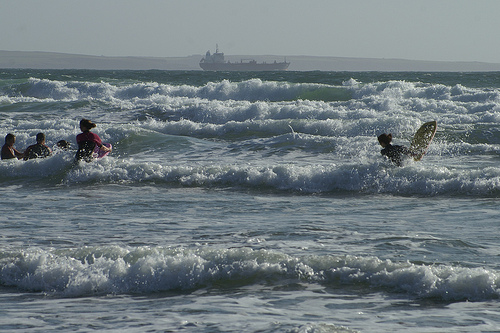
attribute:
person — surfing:
[372, 126, 412, 165]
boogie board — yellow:
[406, 117, 440, 162]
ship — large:
[197, 40, 293, 73]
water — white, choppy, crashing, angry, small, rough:
[6, 69, 497, 331]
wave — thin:
[280, 101, 497, 201]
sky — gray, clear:
[2, 1, 492, 61]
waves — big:
[6, 73, 495, 302]